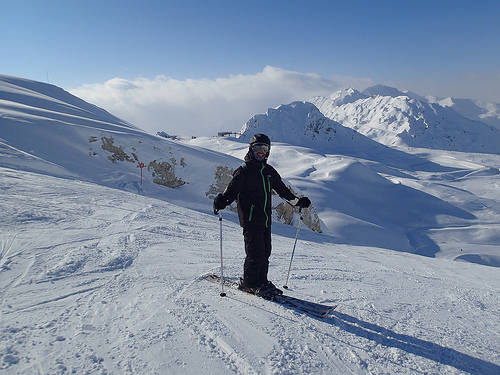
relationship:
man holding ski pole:
[214, 128, 311, 295] [283, 208, 302, 291]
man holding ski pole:
[214, 128, 311, 295] [215, 212, 227, 303]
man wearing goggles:
[214, 128, 311, 295] [250, 142, 270, 152]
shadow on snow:
[311, 315, 496, 375] [3, 169, 498, 375]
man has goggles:
[214, 128, 311, 295] [250, 142, 270, 152]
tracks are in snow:
[189, 260, 365, 329] [3, 169, 498, 375]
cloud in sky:
[78, 64, 499, 150] [1, 1, 499, 116]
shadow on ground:
[311, 315, 496, 375] [1, 199, 498, 373]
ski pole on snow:
[283, 208, 302, 291] [3, 169, 498, 375]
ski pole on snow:
[215, 212, 227, 303] [3, 169, 498, 375]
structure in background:
[214, 130, 246, 142] [0, 119, 494, 160]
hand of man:
[212, 191, 229, 216] [214, 128, 311, 295]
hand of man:
[294, 194, 311, 211] [214, 128, 311, 295]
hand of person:
[212, 191, 229, 216] [214, 128, 311, 295]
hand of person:
[294, 194, 311, 211] [214, 128, 311, 295]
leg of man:
[238, 224, 267, 286] [214, 128, 311, 295]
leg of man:
[260, 227, 273, 285] [214, 128, 311, 295]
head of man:
[246, 131, 270, 162] [214, 128, 311, 295]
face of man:
[252, 141, 268, 161] [214, 128, 311, 295]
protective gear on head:
[248, 133, 276, 149] [246, 131, 270, 162]